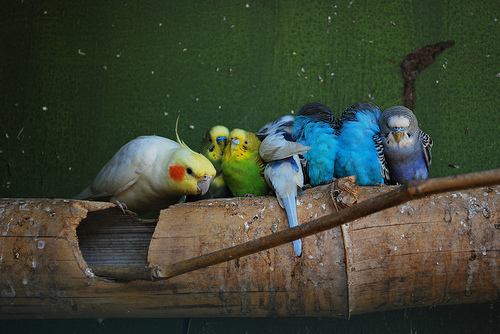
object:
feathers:
[280, 160, 297, 257]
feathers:
[311, 136, 331, 185]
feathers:
[347, 140, 368, 173]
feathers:
[401, 153, 431, 187]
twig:
[81, 248, 280, 289]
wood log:
[3, 175, 473, 325]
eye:
[182, 167, 195, 179]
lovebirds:
[204, 120, 263, 195]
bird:
[380, 103, 427, 188]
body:
[387, 142, 435, 178]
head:
[383, 104, 419, 142]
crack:
[130, 181, 420, 281]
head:
[339, 107, 382, 129]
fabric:
[10, 11, 463, 184]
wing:
[259, 134, 310, 164]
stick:
[110, 171, 471, 272]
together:
[100, 105, 433, 225]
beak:
[190, 175, 213, 195]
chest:
[224, 159, 254, 179]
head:
[165, 146, 216, 196]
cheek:
[163, 160, 187, 186]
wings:
[338, 132, 388, 155]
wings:
[310, 135, 336, 180]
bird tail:
[279, 190, 302, 257]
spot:
[166, 161, 189, 186]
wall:
[3, 1, 148, 116]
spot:
[401, 41, 459, 106]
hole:
[72, 201, 168, 281]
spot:
[30, 231, 50, 260]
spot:
[216, 132, 236, 149]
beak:
[212, 132, 230, 153]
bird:
[197, 125, 236, 197]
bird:
[257, 110, 311, 259]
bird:
[288, 104, 340, 191]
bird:
[335, 101, 393, 187]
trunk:
[3, 169, 495, 332]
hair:
[168, 115, 204, 160]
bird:
[219, 124, 266, 197]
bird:
[73, 131, 234, 227]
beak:
[388, 127, 408, 146]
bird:
[79, 125, 228, 228]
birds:
[87, 93, 436, 257]